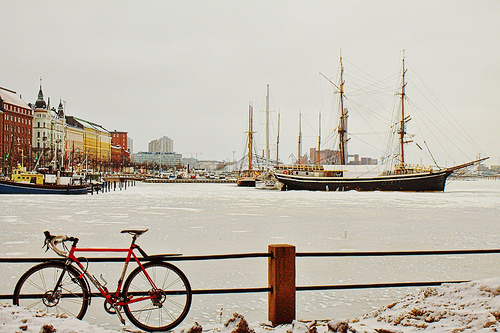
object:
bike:
[14, 226, 195, 331]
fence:
[1, 243, 493, 315]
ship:
[275, 41, 492, 192]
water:
[2, 177, 498, 328]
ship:
[237, 100, 262, 186]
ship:
[1, 126, 108, 198]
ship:
[257, 84, 282, 191]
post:
[266, 243, 298, 325]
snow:
[2, 174, 499, 323]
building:
[28, 73, 68, 161]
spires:
[31, 78, 68, 122]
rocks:
[149, 309, 401, 333]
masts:
[245, 47, 445, 169]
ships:
[239, 157, 485, 191]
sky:
[3, 4, 499, 157]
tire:
[124, 262, 193, 329]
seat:
[120, 228, 147, 236]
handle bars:
[40, 230, 78, 263]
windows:
[3, 105, 35, 155]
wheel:
[13, 261, 90, 319]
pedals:
[95, 274, 124, 327]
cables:
[298, 243, 500, 294]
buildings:
[1, 76, 131, 182]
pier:
[3, 157, 193, 181]